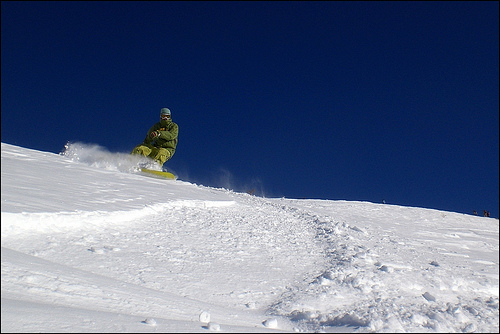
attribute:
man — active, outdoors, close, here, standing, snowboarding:
[137, 101, 194, 160]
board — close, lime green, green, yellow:
[144, 168, 185, 184]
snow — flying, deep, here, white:
[366, 249, 416, 282]